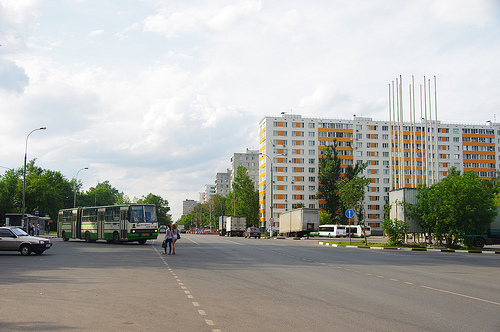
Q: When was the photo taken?
A: Daytime.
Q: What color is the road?
A: Grey.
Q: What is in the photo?
A: Buildings.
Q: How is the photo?
A: Clear.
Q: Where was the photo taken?
A: In a city.